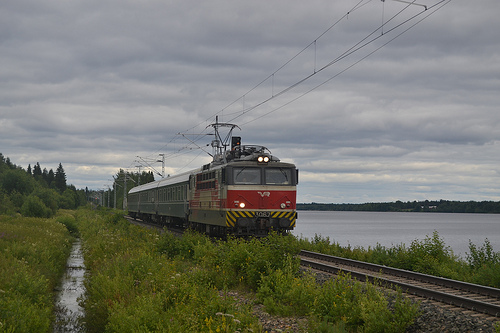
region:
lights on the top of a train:
[252, 150, 275, 165]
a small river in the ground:
[48, 220, 100, 331]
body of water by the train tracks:
[293, 196, 495, 263]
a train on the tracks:
[114, 146, 306, 235]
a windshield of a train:
[232, 168, 290, 185]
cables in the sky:
[122, 3, 437, 172]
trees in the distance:
[3, 153, 155, 202]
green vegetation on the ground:
[5, 193, 498, 330]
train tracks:
[259, 234, 499, 326]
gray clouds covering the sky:
[6, 4, 493, 201]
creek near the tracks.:
[65, 262, 81, 314]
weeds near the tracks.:
[145, 278, 182, 313]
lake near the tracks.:
[377, 214, 430, 230]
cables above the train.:
[255, 93, 298, 105]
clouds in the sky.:
[369, 108, 435, 130]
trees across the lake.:
[447, 200, 472, 210]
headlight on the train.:
[239, 199, 248, 208]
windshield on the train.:
[237, 171, 258, 180]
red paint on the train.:
[251, 196, 271, 208]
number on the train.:
[255, 210, 278, 220]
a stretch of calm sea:
[292, 207, 499, 263]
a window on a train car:
[232, 164, 259, 185]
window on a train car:
[262, 167, 290, 186]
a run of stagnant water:
[57, 233, 87, 326]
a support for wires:
[207, 113, 241, 155]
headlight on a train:
[238, 201, 245, 208]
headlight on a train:
[278, 201, 290, 209]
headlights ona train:
[255, 152, 270, 163]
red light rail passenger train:
[121, 149, 296, 234]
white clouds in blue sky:
[24, 9, 156, 83]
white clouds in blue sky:
[4, 83, 72, 131]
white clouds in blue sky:
[102, 88, 157, 143]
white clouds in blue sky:
[150, 16, 231, 70]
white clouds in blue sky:
[112, 83, 190, 117]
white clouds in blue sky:
[230, 15, 310, 77]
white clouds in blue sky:
[308, 31, 446, 96]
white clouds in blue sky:
[324, 81, 448, 149]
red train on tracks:
[177, 156, 299, 220]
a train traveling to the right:
[114, 148, 310, 246]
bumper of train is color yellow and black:
[224, 203, 302, 236]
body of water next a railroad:
[286, 197, 498, 299]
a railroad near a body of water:
[263, 228, 496, 331]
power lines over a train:
[114, 3, 467, 148]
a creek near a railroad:
[14, 188, 87, 331]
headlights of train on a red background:
[224, 193, 296, 208]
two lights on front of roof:
[227, 153, 297, 177]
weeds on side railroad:
[230, 223, 498, 325]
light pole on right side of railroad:
[80, 160, 141, 215]